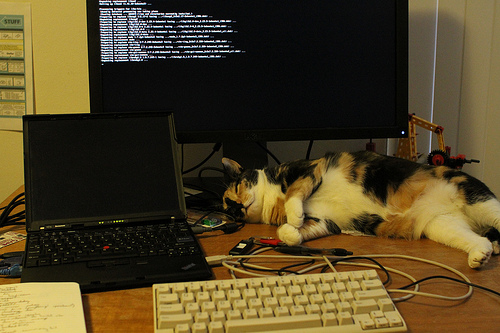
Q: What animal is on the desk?
A: Cat.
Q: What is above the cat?
A: The monitor.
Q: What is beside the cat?
A: The laptop.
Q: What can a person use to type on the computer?
A: The keyboard.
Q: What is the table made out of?
A: Wood.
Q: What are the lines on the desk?
A: Cords.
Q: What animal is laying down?
A: Cat.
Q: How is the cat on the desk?
A: Asleep.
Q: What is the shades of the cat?
A: Black brown and white.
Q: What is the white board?
A: A keyboard.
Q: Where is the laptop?
A: Behind the keyboard.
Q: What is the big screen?
A: A monitor.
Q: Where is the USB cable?
A: On the desk.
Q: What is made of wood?
A: Desk.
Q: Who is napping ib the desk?
A: Cat.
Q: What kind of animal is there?
A: Cat.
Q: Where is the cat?
A: On the table.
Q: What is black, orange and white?
A: The cat.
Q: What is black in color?
A: The laptop.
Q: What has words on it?
A: Screen.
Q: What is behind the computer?
A: A wall.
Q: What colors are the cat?
A: White, black, and orage.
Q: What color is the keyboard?
A: White.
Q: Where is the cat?
A: Under the computer screen.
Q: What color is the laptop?
A: Black.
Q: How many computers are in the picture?
A: Two.